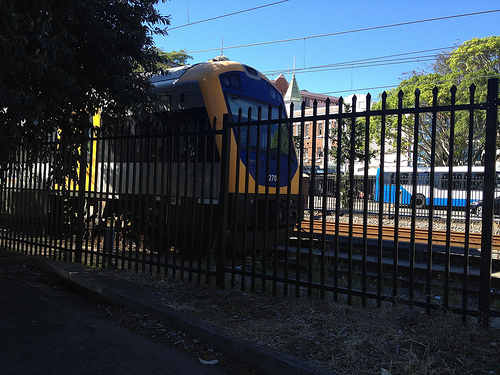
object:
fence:
[0, 72, 500, 329]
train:
[1, 54, 315, 266]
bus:
[372, 159, 500, 219]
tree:
[0, 0, 176, 195]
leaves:
[3, 44, 24, 61]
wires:
[162, 3, 499, 65]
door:
[37, 104, 103, 201]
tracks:
[265, 228, 500, 316]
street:
[0, 232, 314, 375]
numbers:
[260, 170, 287, 188]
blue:
[241, 80, 282, 105]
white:
[145, 165, 214, 190]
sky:
[140, 0, 499, 106]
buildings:
[263, 71, 387, 179]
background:
[0, 0, 499, 374]